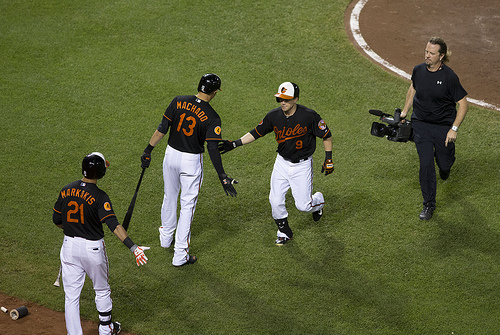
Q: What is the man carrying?
A: Camera.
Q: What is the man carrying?
A: Camera.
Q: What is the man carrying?
A: Camera.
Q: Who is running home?
A: Player.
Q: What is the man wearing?
A: Uniform.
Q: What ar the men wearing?
A: Uniforms.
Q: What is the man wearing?
A: Uniform.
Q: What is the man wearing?
A: Uniform.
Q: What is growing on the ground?
A: Grass.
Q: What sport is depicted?
A: Baseball.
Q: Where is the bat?
A: In the player's hands.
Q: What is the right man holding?
A: A camera.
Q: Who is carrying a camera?
A: The cameraman.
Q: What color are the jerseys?
A: Black.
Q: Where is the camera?
A: With the cameraman.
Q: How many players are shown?
A: Three.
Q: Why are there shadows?
A: From the stadium lights.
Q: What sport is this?
A: Baseball.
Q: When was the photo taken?
A: During the game.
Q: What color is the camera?
A: Black.